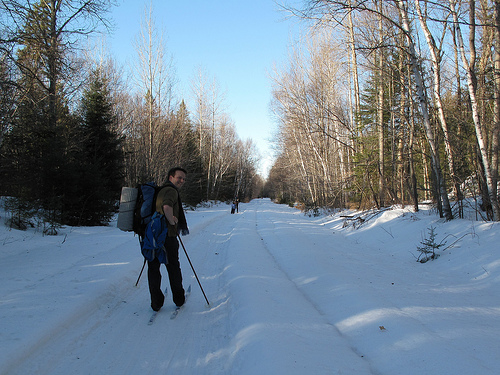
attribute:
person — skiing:
[142, 162, 188, 308]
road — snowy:
[1, 202, 389, 375]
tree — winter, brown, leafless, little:
[135, 11, 164, 206]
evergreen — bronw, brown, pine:
[68, 71, 129, 231]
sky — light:
[1, 1, 490, 176]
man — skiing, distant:
[229, 195, 241, 215]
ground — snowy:
[0, 199, 496, 372]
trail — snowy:
[74, 165, 232, 369]